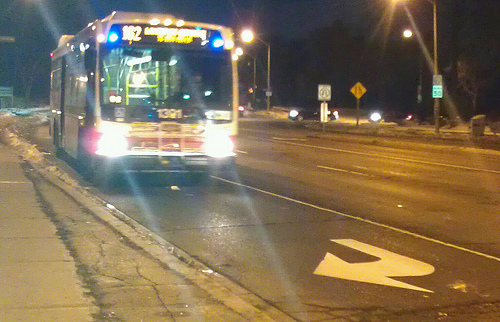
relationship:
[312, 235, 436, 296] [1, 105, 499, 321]
arrow on ground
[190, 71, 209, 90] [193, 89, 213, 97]
driver behind wheel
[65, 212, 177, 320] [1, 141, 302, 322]
cracks in sidewalk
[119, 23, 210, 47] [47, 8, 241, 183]
screen on bus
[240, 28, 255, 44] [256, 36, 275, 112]
light on top of pole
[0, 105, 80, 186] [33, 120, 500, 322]
snow on side of road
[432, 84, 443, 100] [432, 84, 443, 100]
sign has sign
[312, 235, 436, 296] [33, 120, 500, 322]
arrow on road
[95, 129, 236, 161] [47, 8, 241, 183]
headlights on bus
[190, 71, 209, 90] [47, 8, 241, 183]
driver steering bus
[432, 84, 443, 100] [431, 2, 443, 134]
sign attached to pole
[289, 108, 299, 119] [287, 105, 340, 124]
headlight on car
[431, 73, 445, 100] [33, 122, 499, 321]
signs on side of street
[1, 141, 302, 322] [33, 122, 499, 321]
sidewalk by street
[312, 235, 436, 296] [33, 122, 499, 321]
arrow on street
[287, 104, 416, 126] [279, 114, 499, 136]
cars getting off freeway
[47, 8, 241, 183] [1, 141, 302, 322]
bus by sidewalk